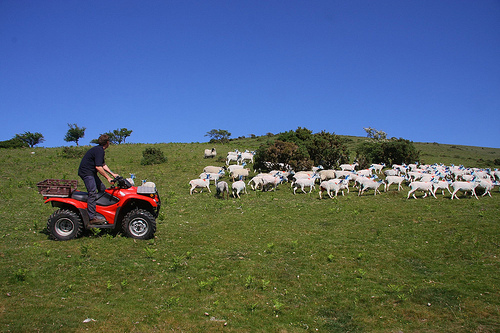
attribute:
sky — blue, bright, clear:
[1, 1, 499, 149]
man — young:
[77, 132, 121, 224]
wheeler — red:
[39, 173, 161, 239]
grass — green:
[0, 135, 498, 330]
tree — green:
[62, 122, 85, 148]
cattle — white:
[189, 146, 500, 201]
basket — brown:
[37, 178, 78, 197]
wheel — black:
[47, 209, 85, 239]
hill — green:
[3, 132, 499, 331]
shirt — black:
[78, 144, 105, 178]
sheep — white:
[358, 177, 385, 198]